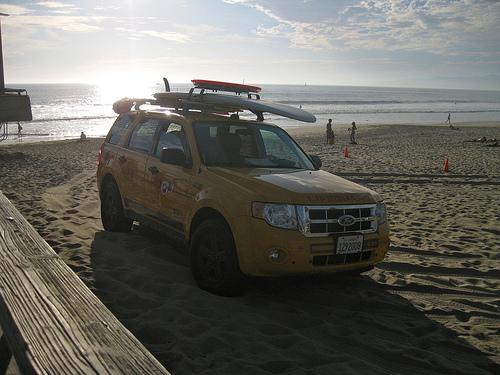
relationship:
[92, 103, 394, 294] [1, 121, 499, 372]
suv on beach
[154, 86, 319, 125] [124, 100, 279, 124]
surfboard on roof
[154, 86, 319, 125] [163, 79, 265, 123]
surfboard on rack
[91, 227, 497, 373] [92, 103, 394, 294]
shadow of suv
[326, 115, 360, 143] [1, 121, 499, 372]
people on beach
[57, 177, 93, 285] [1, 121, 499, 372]
footprints on beach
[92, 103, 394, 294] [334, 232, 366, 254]
suv has tag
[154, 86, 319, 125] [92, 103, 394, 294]
surfboard on suv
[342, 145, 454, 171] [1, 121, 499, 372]
cones on beach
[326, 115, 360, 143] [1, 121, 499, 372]
people walking on beach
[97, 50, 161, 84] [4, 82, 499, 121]
sun behind ocean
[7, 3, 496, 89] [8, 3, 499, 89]
clouds in sky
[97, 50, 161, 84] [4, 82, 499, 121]
sun on ocean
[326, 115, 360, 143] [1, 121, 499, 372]
people playing on beach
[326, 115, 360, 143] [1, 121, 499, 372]
people running on beach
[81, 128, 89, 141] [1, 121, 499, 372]
person sitting on beach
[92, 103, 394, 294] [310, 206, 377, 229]
suv has grill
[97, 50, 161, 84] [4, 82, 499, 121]
sun reflecting on ocean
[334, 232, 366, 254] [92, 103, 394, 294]
tag on suv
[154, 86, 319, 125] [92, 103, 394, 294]
surfboard attached to suv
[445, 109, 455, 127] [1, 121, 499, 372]
person running on beach